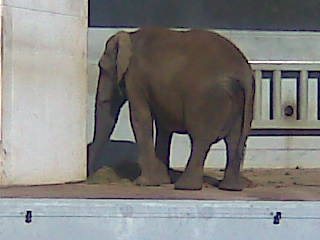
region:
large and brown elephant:
[97, 18, 272, 185]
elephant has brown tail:
[229, 60, 275, 186]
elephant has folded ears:
[98, 37, 133, 72]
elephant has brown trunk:
[70, 72, 132, 178]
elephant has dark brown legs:
[125, 85, 237, 186]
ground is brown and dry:
[252, 171, 310, 194]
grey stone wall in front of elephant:
[76, 202, 268, 239]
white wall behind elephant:
[244, 30, 297, 60]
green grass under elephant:
[92, 157, 150, 196]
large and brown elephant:
[103, 36, 244, 193]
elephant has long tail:
[228, 65, 265, 161]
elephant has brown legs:
[120, 99, 217, 195]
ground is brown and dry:
[255, 171, 318, 204]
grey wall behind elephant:
[258, 34, 314, 134]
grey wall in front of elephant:
[29, 204, 263, 236]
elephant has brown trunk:
[80, 74, 132, 186]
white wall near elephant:
[18, 44, 83, 156]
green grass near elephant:
[78, 151, 126, 198]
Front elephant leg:
[135, 177, 159, 184]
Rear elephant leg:
[175, 184, 201, 188]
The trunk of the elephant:
[96, 112, 107, 137]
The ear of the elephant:
[120, 47, 125, 68]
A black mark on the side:
[25, 214, 30, 220]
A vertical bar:
[272, 77, 277, 118]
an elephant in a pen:
[77, 13, 295, 206]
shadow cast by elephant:
[84, 128, 216, 201]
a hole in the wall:
[279, 95, 299, 121]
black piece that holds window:
[14, 210, 48, 226]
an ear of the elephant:
[103, 29, 156, 104]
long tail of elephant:
[225, 69, 256, 195]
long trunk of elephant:
[82, 77, 136, 190]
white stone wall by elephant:
[5, 7, 115, 189]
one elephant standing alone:
[82, 15, 287, 198]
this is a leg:
[124, 99, 164, 185]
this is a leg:
[164, 129, 219, 201]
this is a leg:
[218, 140, 251, 204]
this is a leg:
[153, 121, 175, 186]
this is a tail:
[233, 77, 262, 175]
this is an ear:
[114, 28, 139, 91]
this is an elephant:
[89, 23, 264, 209]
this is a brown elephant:
[87, 24, 268, 203]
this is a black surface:
[89, 0, 310, 29]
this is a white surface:
[7, 13, 85, 180]